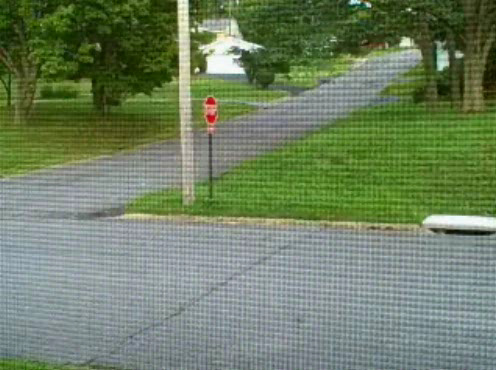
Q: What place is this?
A: It is a field.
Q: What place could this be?
A: It is a field.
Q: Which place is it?
A: It is a field.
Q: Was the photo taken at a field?
A: Yes, it was taken in a field.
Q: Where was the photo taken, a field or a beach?
A: It was taken at a field.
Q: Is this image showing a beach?
A: No, the picture is showing a field.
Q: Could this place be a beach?
A: No, it is a field.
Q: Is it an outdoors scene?
A: Yes, it is outdoors.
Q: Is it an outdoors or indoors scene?
A: It is outdoors.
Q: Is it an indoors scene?
A: No, it is outdoors.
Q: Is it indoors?
A: No, it is outdoors.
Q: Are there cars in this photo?
A: No, there are no cars.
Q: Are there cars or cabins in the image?
A: No, there are no cars or cabins.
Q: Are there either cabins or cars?
A: No, there are no cars or cabins.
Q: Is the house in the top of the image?
A: Yes, the house is in the top of the image.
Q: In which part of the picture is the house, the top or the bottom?
A: The house is in the top of the image.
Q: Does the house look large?
A: Yes, the house is large.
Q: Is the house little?
A: No, the house is large.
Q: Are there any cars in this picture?
A: No, there are no cars.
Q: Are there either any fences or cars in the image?
A: No, there are no cars or fences.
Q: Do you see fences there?
A: No, there are no fences.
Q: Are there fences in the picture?
A: No, there are no fences.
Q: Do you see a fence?
A: No, there are no fences.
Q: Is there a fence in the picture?
A: No, there are no fences.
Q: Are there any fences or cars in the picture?
A: No, there are no fences or cars.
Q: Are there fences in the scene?
A: No, there are no fences.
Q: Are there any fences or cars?
A: No, there are no fences or cars.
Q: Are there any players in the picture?
A: No, there are no players.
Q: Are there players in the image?
A: No, there are no players.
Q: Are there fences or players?
A: No, there are no players or fences.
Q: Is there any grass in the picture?
A: Yes, there is grass.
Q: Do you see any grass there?
A: Yes, there is grass.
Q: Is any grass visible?
A: Yes, there is grass.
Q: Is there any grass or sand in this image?
A: Yes, there is grass.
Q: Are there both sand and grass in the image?
A: No, there is grass but no sand.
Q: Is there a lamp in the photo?
A: No, there are no lamps.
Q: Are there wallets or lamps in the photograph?
A: No, there are no lamps or wallets.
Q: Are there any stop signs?
A: Yes, there is a stop sign.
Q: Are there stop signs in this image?
A: Yes, there is a stop sign.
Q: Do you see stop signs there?
A: Yes, there is a stop sign.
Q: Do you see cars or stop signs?
A: Yes, there is a stop sign.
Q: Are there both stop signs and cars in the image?
A: No, there is a stop sign but no cars.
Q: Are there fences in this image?
A: No, there are no fences.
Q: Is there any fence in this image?
A: No, there are no fences.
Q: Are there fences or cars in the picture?
A: No, there are no fences or cars.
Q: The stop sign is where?
A: The stop sign is on the grass.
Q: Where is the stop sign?
A: The stop sign is on the grass.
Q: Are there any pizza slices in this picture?
A: No, there are no pizza slices.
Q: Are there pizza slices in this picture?
A: No, there are no pizza slices.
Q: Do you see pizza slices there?
A: No, there are no pizza slices.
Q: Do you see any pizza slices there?
A: No, there are no pizza slices.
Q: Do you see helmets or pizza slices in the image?
A: No, there are no pizza slices or helmets.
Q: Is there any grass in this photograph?
A: Yes, there is grass.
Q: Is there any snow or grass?
A: Yes, there is grass.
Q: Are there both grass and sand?
A: No, there is grass but no sand.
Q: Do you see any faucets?
A: No, there are no faucets.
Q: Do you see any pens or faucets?
A: No, there are no faucets or pens.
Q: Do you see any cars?
A: No, there are no cars.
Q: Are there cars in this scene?
A: No, there are no cars.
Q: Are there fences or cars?
A: No, there are no cars or fences.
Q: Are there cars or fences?
A: No, there are no cars or fences.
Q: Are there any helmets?
A: No, there are no helmets.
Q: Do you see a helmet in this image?
A: No, there are no helmets.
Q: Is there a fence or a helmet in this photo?
A: No, there are no helmets or fences.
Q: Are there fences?
A: No, there are no fences.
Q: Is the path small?
A: Yes, the path is small.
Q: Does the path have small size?
A: Yes, the path is small.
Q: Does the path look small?
A: Yes, the path is small.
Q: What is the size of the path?
A: The path is small.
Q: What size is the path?
A: The path is small.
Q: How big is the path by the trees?
A: The path is small.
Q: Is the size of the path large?
A: No, the path is small.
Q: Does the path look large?
A: No, the path is small.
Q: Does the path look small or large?
A: The path is small.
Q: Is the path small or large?
A: The path is small.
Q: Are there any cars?
A: No, there are no cars.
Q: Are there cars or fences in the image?
A: No, there are no cars or fences.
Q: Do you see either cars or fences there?
A: No, there are no cars or fences.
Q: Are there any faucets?
A: No, there are no faucets.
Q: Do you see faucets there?
A: No, there are no faucets.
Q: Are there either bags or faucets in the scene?
A: No, there are no faucets or bags.